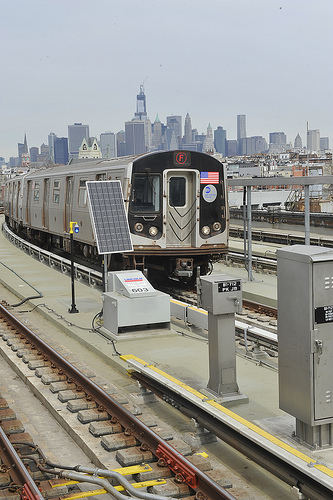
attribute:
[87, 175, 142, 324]
solar panel — rectangular 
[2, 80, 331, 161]
tall buildings — tall 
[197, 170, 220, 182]
american flag — small 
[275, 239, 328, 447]
electrical box — grey 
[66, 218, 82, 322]
thin pole — thin 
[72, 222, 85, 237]
blue light — blue 